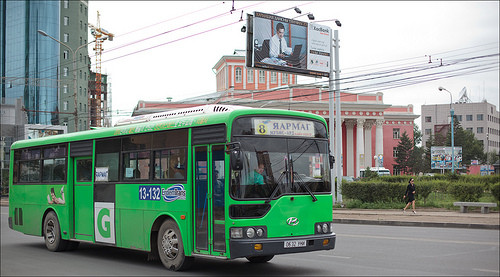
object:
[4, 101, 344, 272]
bus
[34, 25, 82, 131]
light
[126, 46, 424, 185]
building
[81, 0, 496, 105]
sky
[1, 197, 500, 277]
road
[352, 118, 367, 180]
columns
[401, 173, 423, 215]
woman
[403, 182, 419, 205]
dress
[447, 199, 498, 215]
bench